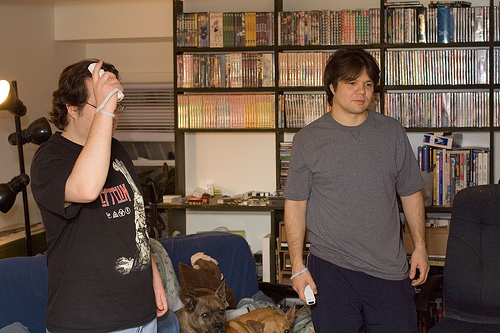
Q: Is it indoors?
A: Yes, it is indoors.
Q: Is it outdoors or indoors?
A: It is indoors.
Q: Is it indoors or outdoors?
A: It is indoors.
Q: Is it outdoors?
A: No, it is indoors.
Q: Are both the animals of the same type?
A: Yes, all the animals are dogs.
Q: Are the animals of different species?
A: No, all the animals are dogs.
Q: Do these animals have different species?
A: No, all the animals are dogs.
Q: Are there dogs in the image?
A: Yes, there is a dog.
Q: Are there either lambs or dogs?
A: Yes, there is a dog.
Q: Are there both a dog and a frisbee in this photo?
A: No, there is a dog but no frisbees.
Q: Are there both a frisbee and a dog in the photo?
A: No, there is a dog but no frisbees.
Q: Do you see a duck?
A: No, there are no ducks.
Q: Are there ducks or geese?
A: No, there are no ducks or geese.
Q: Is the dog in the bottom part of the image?
A: Yes, the dog is in the bottom of the image.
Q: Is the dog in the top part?
A: No, the dog is in the bottom of the image.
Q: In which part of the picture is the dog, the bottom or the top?
A: The dog is in the bottom of the image.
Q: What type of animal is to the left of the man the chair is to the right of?
A: The animal is a dog.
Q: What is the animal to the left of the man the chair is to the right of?
A: The animal is a dog.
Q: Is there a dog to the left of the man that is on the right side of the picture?
A: Yes, there is a dog to the left of the man.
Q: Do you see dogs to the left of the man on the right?
A: Yes, there is a dog to the left of the man.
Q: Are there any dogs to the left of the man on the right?
A: Yes, there is a dog to the left of the man.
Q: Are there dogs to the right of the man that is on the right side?
A: No, the dog is to the left of the man.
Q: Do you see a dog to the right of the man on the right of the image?
A: No, the dog is to the left of the man.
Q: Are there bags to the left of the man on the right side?
A: No, there is a dog to the left of the man.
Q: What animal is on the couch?
A: The dog is on the couch.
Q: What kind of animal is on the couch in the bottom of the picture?
A: The animal is a dog.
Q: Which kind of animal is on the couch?
A: The animal is a dog.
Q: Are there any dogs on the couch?
A: Yes, there is a dog on the couch.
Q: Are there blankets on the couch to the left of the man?
A: No, there is a dog on the couch.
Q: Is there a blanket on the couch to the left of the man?
A: No, there is a dog on the couch.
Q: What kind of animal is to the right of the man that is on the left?
A: The animal is a dog.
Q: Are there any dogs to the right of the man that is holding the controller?
A: Yes, there is a dog to the right of the man.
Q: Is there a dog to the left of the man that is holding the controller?
A: No, the dog is to the right of the man.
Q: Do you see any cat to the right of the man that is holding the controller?
A: No, there is a dog to the right of the man.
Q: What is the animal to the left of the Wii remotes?
A: The animal is a dog.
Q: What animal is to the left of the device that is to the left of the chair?
A: The animal is a dog.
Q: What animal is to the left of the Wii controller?
A: The animal is a dog.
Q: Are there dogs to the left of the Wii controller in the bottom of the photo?
A: Yes, there is a dog to the left of the Wii remotes.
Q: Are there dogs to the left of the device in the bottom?
A: Yes, there is a dog to the left of the Wii remotes.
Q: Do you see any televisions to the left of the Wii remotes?
A: No, there is a dog to the left of the Wii remotes.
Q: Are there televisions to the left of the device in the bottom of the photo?
A: No, there is a dog to the left of the Wii remotes.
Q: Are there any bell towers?
A: No, there are no bell towers.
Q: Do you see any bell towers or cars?
A: No, there are no bell towers or cars.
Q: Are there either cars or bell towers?
A: No, there are no bell towers or cars.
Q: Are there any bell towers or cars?
A: No, there are no bell towers or cars.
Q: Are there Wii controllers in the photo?
A: Yes, there is a Wii controller.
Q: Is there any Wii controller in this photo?
A: Yes, there is a Wii controller.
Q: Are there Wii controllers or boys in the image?
A: Yes, there is a Wii controller.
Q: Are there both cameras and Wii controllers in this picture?
A: No, there is a Wii controller but no cameras.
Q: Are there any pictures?
A: No, there are no pictures.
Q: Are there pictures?
A: No, there are no pictures.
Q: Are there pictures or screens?
A: No, there are no pictures or screens.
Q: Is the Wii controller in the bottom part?
A: Yes, the Wii controller is in the bottom of the image.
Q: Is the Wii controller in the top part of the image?
A: No, the Wii controller is in the bottom of the image.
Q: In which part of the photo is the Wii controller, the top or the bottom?
A: The Wii controller is in the bottom of the image.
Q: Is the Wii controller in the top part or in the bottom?
A: The Wii controller is in the bottom of the image.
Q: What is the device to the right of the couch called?
A: The device is a Wii controller.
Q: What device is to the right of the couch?
A: The device is a Wii controller.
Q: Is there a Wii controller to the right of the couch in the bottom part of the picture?
A: Yes, there is a Wii controller to the right of the couch.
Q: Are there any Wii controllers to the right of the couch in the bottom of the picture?
A: Yes, there is a Wii controller to the right of the couch.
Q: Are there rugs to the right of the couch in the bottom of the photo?
A: No, there is a Wii controller to the right of the couch.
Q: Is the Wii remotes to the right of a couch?
A: Yes, the Wii remotes is to the right of a couch.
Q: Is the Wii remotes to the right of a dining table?
A: No, the Wii remotes is to the right of a couch.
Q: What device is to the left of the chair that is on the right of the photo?
A: The device is a Wii controller.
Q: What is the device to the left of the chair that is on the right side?
A: The device is a Wii controller.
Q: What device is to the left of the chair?
A: The device is a Wii controller.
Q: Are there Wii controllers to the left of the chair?
A: Yes, there is a Wii controller to the left of the chair.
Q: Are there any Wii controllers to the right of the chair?
A: No, the Wii controller is to the left of the chair.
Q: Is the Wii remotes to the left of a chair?
A: Yes, the Wii remotes is to the left of a chair.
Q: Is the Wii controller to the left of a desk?
A: No, the Wii controller is to the left of a chair.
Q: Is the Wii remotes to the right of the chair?
A: No, the Wii remotes is to the left of the chair.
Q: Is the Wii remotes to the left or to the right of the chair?
A: The Wii remotes is to the left of the chair.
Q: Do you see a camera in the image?
A: No, there are no cameras.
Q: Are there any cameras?
A: No, there are no cameras.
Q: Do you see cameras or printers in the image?
A: No, there are no cameras or printers.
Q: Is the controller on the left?
A: Yes, the controller is on the left of the image.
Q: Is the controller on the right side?
A: No, the controller is on the left of the image.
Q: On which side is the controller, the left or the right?
A: The controller is on the left of the image.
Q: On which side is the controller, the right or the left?
A: The controller is on the left of the image.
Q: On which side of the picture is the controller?
A: The controller is on the left of the image.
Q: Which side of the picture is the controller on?
A: The controller is on the left of the image.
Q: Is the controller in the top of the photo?
A: Yes, the controller is in the top of the image.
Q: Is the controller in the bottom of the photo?
A: No, the controller is in the top of the image.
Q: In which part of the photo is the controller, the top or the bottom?
A: The controller is in the top of the image.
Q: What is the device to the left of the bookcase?
A: The device is a controller.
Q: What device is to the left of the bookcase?
A: The device is a controller.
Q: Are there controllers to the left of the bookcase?
A: Yes, there is a controller to the left of the bookcase.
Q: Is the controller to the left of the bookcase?
A: Yes, the controller is to the left of the bookcase.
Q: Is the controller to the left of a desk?
A: No, the controller is to the left of the bookcase.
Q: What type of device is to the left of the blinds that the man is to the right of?
A: The device is a controller.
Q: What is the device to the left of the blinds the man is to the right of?
A: The device is a controller.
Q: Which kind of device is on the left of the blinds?
A: The device is a controller.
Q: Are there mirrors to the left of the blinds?
A: No, there is a controller to the left of the blinds.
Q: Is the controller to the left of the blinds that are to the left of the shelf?
A: Yes, the controller is to the left of the blinds.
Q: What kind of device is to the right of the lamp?
A: The device is a controller.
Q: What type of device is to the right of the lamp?
A: The device is a controller.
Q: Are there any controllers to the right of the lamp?
A: Yes, there is a controller to the right of the lamp.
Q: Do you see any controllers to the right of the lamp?
A: Yes, there is a controller to the right of the lamp.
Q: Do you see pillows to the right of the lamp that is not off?
A: No, there is a controller to the right of the lamp.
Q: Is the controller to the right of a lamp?
A: Yes, the controller is to the right of a lamp.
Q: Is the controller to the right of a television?
A: No, the controller is to the right of a lamp.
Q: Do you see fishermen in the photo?
A: No, there are no fishermen.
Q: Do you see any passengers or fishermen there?
A: No, there are no fishermen or passengers.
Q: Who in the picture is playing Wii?
A: The man is playing wii.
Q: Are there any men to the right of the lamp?
A: Yes, there is a man to the right of the lamp.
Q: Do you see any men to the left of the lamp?
A: No, the man is to the right of the lamp.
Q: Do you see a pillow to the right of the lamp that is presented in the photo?
A: No, there is a man to the right of the lamp.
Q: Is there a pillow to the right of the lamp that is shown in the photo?
A: No, there is a man to the right of the lamp.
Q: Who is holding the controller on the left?
A: The man is holding the controller.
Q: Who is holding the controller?
A: The man is holding the controller.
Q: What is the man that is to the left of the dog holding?
A: The man is holding the controller.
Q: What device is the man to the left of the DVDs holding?
A: The man is holding the controller.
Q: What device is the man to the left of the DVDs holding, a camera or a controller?
A: The man is holding a controller.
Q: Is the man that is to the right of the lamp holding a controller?
A: Yes, the man is holding a controller.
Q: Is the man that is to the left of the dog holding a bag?
A: No, the man is holding a controller.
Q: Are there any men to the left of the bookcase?
A: Yes, there is a man to the left of the bookcase.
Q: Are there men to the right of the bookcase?
A: No, the man is to the left of the bookcase.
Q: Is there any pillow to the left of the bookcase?
A: No, there is a man to the left of the bookcase.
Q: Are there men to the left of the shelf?
A: Yes, there is a man to the left of the shelf.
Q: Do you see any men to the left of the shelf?
A: Yes, there is a man to the left of the shelf.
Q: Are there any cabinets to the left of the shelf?
A: No, there is a man to the left of the shelf.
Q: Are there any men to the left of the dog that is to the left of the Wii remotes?
A: Yes, there is a man to the left of the dog.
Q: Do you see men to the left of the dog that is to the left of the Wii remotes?
A: Yes, there is a man to the left of the dog.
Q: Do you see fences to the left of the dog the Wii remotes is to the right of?
A: No, there is a man to the left of the dog.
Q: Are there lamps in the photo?
A: Yes, there is a lamp.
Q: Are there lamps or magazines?
A: Yes, there is a lamp.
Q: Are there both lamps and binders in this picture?
A: No, there is a lamp but no binders.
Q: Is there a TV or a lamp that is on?
A: Yes, the lamp is on.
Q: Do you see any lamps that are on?
A: Yes, there is a lamp that is on.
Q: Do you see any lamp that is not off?
A: Yes, there is a lamp that is on .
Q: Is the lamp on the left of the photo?
A: Yes, the lamp is on the left of the image.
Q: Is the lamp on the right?
A: No, the lamp is on the left of the image.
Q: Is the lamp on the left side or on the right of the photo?
A: The lamp is on the left of the image.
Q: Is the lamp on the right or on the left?
A: The lamp is on the left of the image.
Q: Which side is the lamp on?
A: The lamp is on the left of the image.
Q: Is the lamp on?
A: Yes, the lamp is on.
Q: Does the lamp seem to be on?
A: Yes, the lamp is on.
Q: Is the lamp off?
A: No, the lamp is on.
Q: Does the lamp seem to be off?
A: No, the lamp is on.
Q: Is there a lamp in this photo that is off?
A: No, there is a lamp but it is on.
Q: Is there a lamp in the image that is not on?
A: No, there is a lamp but it is on.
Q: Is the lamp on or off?
A: The lamp is on.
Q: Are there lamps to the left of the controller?
A: Yes, there is a lamp to the left of the controller.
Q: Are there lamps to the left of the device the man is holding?
A: Yes, there is a lamp to the left of the controller.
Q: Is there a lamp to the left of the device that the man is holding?
A: Yes, there is a lamp to the left of the controller.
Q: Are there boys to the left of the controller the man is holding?
A: No, there is a lamp to the left of the controller.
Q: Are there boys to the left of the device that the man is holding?
A: No, there is a lamp to the left of the controller.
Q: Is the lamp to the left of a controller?
A: Yes, the lamp is to the left of a controller.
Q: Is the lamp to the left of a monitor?
A: No, the lamp is to the left of a controller.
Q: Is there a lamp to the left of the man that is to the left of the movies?
A: Yes, there is a lamp to the left of the man.